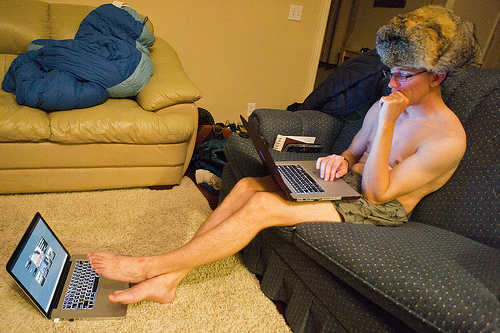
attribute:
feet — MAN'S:
[85, 247, 171, 307]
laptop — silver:
[237, 109, 362, 205]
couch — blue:
[215, 63, 497, 330]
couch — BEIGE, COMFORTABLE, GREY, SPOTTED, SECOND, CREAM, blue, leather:
[3, 2, 190, 184]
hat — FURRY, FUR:
[373, 9, 477, 69]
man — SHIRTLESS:
[85, 10, 456, 328]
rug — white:
[2, 190, 282, 331]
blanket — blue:
[9, 1, 172, 116]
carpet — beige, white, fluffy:
[2, 191, 284, 330]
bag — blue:
[5, 4, 162, 118]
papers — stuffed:
[271, 132, 318, 151]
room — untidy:
[4, 3, 492, 310]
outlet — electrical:
[242, 97, 256, 114]